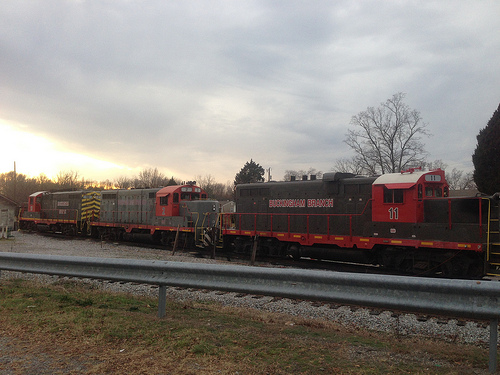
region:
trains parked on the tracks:
[14, 164, 486, 272]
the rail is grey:
[40, 245, 473, 346]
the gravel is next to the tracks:
[245, 297, 429, 336]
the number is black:
[370, 198, 416, 225]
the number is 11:
[376, 197, 413, 229]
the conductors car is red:
[357, 152, 455, 227]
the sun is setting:
[2, 133, 123, 190]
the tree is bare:
[327, 87, 432, 171]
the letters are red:
[242, 196, 338, 209]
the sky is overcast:
[21, 33, 318, 170]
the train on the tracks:
[18, 166, 496, 251]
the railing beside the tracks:
[7, 248, 498, 315]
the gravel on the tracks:
[265, 301, 407, 333]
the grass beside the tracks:
[32, 292, 442, 374]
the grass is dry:
[51, 308, 319, 370]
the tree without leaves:
[353, 93, 421, 161]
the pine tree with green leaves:
[466, 101, 498, 196]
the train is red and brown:
[18, 186, 458, 259]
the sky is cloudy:
[97, 10, 436, 126]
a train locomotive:
[227, 157, 495, 308]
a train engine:
[223, 151, 493, 284]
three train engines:
[26, 166, 499, 279]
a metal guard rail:
[18, 255, 494, 333]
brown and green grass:
[15, 298, 203, 363]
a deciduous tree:
[342, 83, 440, 167]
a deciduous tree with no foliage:
[341, 86, 435, 176]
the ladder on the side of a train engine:
[185, 205, 211, 248]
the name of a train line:
[265, 195, 341, 210]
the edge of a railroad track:
[183, 286, 497, 341]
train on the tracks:
[14, 157, 497, 269]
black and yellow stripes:
[77, 196, 104, 223]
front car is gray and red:
[226, 163, 494, 266]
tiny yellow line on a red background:
[329, 233, 350, 247]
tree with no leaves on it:
[336, 95, 446, 177]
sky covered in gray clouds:
[0, 6, 495, 186]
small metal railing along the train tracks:
[3, 242, 498, 334]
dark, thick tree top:
[462, 106, 497, 192]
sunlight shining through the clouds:
[1, 121, 128, 181]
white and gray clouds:
[2, 3, 476, 178]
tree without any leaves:
[340, 89, 433, 173]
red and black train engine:
[229, 173, 490, 281]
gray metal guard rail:
[2, 246, 499, 353]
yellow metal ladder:
[485, 193, 499, 290]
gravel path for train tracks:
[4, 223, 499, 348]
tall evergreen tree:
[471, 99, 498, 194]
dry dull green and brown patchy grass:
[1, 280, 497, 371]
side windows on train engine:
[383, 185, 403, 204]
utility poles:
[265, 165, 274, 180]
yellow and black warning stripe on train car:
[81, 190, 101, 226]